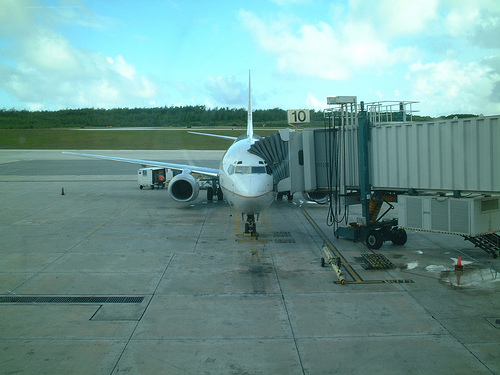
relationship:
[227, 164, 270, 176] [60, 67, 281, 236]
windshield on airplane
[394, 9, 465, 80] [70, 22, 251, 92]
clouds in sky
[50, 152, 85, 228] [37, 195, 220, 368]
cone on concrete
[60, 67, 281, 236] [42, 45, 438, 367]
airplane at airport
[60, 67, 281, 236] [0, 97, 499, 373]
airplane at an airport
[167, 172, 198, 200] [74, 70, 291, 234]
engine on airplane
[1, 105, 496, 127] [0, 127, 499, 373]
trees behind airport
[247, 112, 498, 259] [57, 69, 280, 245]
passenger unloader of plane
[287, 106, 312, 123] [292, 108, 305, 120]
sign with 10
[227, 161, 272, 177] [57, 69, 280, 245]
window on plane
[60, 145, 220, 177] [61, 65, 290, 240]
wing on plane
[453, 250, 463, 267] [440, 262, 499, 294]
cone in puddle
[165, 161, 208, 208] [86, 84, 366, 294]
engine of plane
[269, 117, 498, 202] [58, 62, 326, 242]
walkway to plane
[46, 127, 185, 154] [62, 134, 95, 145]
field of green grass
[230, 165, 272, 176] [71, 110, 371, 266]
windows of plane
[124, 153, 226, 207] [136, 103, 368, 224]
van beside plane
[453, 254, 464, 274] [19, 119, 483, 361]
orange cone on ground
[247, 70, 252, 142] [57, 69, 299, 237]
tail on airplane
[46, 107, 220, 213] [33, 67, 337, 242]
wing on airplane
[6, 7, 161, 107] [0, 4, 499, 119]
cloud in sky